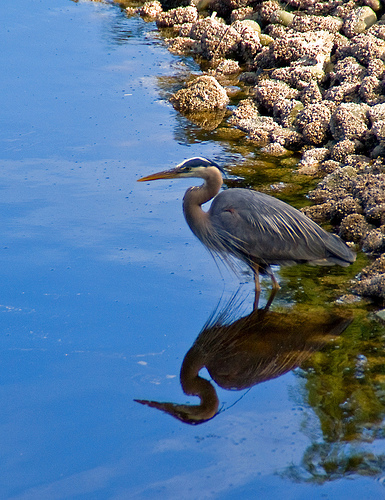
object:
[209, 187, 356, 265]
body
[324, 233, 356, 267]
tail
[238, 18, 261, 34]
rocks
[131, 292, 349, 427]
reflection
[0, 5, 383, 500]
water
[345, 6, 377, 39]
rocks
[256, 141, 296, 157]
coral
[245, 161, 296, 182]
algae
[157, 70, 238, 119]
growth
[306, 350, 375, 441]
moss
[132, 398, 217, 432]
bird's head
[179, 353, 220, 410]
neck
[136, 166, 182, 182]
beak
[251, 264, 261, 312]
long legs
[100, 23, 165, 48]
ripples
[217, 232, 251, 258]
feathers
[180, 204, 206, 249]
birds' chest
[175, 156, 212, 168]
black stripe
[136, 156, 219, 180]
birds head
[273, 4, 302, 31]
rocks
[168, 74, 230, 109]
growth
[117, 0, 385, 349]
shore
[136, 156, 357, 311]
aquatic bird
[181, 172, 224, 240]
long neck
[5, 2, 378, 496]
lake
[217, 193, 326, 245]
long feathers